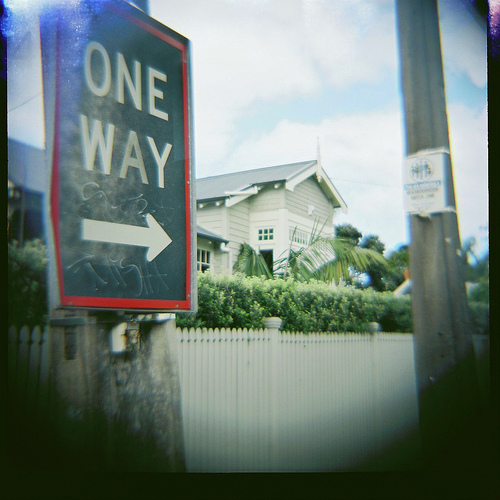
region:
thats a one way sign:
[41, 0, 199, 320]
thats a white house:
[197, 134, 352, 317]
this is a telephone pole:
[391, 0, 498, 493]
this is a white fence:
[2, 330, 497, 497]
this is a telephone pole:
[44, 0, 191, 498]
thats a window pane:
[197, 246, 212, 277]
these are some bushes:
[177, 269, 411, 335]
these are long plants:
[231, 209, 391, 281]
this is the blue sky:
[2, 1, 495, 284]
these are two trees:
[332, 220, 387, 253]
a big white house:
[203, 134, 358, 289]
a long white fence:
[216, 328, 378, 456]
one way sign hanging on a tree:
[61, 15, 197, 321]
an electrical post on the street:
[393, 5, 468, 347]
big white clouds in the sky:
[267, 30, 389, 120]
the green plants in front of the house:
[240, 258, 363, 308]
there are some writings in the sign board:
[71, 244, 175, 301]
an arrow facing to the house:
[75, 197, 176, 280]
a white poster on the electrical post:
[393, 144, 451, 223]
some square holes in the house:
[258, 225, 277, 245]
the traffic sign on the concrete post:
[46, 5, 193, 309]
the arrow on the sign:
[80, 200, 172, 261]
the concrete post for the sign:
[54, 310, 185, 472]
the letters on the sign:
[67, 245, 173, 301]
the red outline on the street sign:
[172, 45, 194, 310]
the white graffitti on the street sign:
[74, 175, 147, 223]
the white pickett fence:
[191, 325, 411, 465]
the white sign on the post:
[397, 154, 445, 220]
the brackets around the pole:
[440, 146, 453, 218]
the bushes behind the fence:
[199, 273, 413, 333]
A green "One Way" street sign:
[48, 2, 196, 312]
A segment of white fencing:
[181, 317, 403, 464]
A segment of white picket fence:
[189, 317, 364, 469]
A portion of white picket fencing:
[201, 312, 374, 468]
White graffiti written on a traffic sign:
[61, 177, 188, 309]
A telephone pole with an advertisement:
[392, 12, 469, 372]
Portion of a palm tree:
[284, 223, 371, 283]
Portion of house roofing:
[202, 158, 322, 189]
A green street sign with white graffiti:
[24, 0, 206, 323]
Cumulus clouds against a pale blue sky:
[210, 15, 382, 155]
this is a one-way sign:
[40, 7, 249, 336]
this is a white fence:
[174, 315, 437, 474]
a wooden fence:
[171, 310, 428, 476]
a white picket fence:
[177, 318, 425, 482]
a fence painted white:
[177, 311, 419, 485]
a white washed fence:
[173, 308, 421, 477]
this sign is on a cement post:
[389, 137, 452, 231]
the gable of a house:
[211, 125, 354, 285]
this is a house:
[195, 150, 352, 282]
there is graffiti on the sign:
[45, 29, 192, 296]